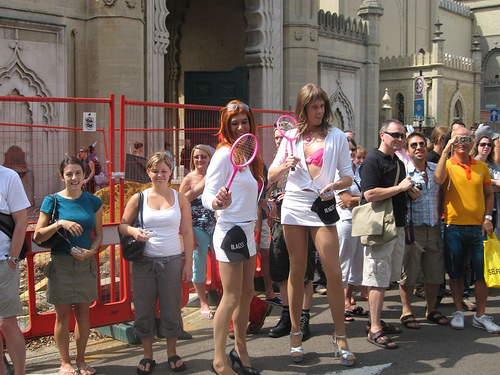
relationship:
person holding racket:
[200, 98, 265, 373] [217, 131, 259, 210]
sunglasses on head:
[224, 101, 250, 117] [215, 96, 252, 148]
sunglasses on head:
[383, 128, 404, 138] [373, 113, 407, 154]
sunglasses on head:
[410, 138, 427, 152] [407, 129, 425, 161]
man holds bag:
[437, 125, 499, 334] [480, 230, 498, 289]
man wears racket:
[437, 125, 499, 334] [217, 131, 259, 210]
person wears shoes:
[268, 82, 359, 361] [284, 326, 359, 366]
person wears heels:
[200, 98, 265, 373] [227, 348, 262, 375]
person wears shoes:
[123, 145, 205, 356] [361, 310, 400, 352]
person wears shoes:
[42, 155, 112, 374] [130, 349, 189, 371]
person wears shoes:
[352, 116, 421, 344] [49, 354, 101, 374]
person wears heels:
[200, 98, 265, 373] [209, 361, 240, 373]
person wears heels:
[204, 98, 266, 373] [227, 348, 255, 373]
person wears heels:
[204, 98, 266, 373] [209, 361, 219, 373]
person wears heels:
[352, 116, 421, 344] [227, 348, 262, 375]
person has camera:
[29, 156, 102, 374] [48, 218, 90, 256]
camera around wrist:
[48, 218, 90, 256] [50, 216, 67, 230]